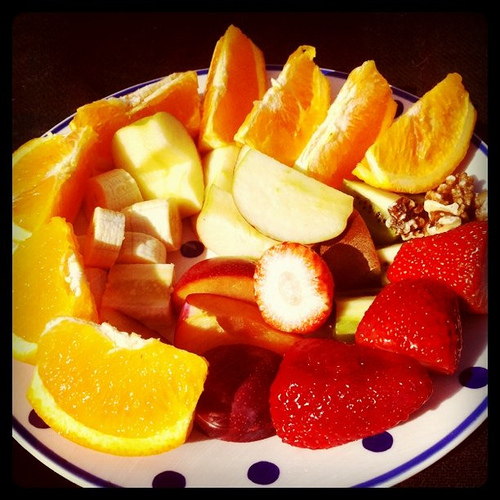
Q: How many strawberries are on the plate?
A: Three.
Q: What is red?
A: Strawberries.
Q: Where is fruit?
A: On a plate.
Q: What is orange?
A: Orange slices.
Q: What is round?
A: Plate.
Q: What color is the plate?
A: White and blue.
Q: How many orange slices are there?
A: Eight.